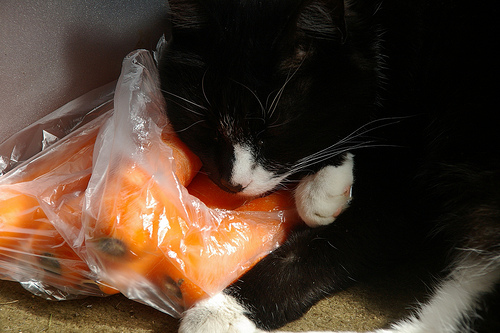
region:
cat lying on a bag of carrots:
[3, 4, 492, 329]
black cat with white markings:
[150, 4, 490, 328]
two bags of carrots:
[2, 95, 204, 300]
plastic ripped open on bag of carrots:
[157, 124, 223, 221]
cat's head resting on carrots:
[149, 15, 384, 193]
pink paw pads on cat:
[329, 183, 355, 229]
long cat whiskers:
[281, 108, 413, 171]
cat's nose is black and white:
[215, 138, 253, 195]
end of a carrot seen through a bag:
[92, 228, 134, 263]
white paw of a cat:
[290, 156, 357, 231]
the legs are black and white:
[175, 277, 257, 331]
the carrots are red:
[25, 131, 256, 282]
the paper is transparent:
[20, 105, 251, 292]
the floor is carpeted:
[340, 290, 390, 325]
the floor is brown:
[335, 280, 395, 320]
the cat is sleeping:
[155, 35, 497, 325]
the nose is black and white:
[210, 147, 257, 197]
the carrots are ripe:
[0, 143, 241, 296]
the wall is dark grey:
[16, 76, 67, 105]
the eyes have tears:
[247, 125, 275, 150]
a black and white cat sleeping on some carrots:
[148, 0, 496, 329]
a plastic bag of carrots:
[3, 20, 163, 315]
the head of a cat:
[147, 0, 366, 196]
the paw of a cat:
[293, 160, 353, 227]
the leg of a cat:
[153, 223, 383, 331]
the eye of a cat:
[263, 109, 300, 139]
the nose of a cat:
[224, 172, 255, 194]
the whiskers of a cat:
[298, 115, 395, 171]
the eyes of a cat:
[182, 108, 291, 140]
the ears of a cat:
[161, 0, 351, 49]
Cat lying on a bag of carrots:
[0, 0, 498, 332]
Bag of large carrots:
[0, 33, 301, 318]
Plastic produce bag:
[0, 32, 297, 321]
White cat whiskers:
[291, 110, 412, 177]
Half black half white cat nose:
[212, 140, 257, 191]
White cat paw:
[292, 149, 357, 229]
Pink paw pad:
[331, 205, 345, 218]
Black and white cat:
[154, 0, 498, 330]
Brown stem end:
[94, 234, 129, 258]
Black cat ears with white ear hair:
[160, 2, 344, 48]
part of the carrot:
[162, 132, 186, 184]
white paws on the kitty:
[295, 162, 353, 230]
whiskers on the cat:
[304, 134, 374, 152]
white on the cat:
[447, 264, 487, 311]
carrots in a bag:
[5, 98, 163, 306]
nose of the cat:
[213, 168, 256, 199]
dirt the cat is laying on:
[324, 302, 363, 326]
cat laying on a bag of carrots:
[137, 3, 499, 332]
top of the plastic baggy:
[24, 125, 64, 147]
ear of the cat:
[304, 4, 356, 40]